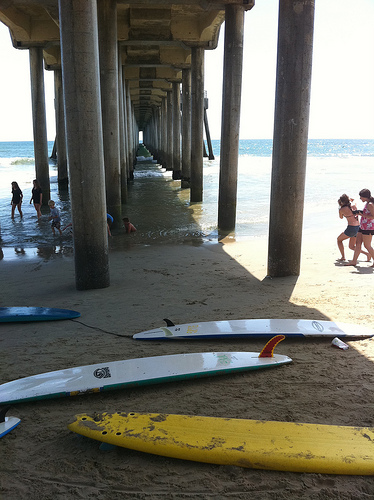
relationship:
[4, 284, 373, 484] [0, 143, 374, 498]
surfboards on beach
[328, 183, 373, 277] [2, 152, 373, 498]
girls walking on beach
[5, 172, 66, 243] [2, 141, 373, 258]
people in water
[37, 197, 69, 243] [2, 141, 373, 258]
child in water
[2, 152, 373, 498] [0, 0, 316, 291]
beach under dock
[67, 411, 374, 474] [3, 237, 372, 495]
surfboard on sand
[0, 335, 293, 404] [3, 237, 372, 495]
surfboard on sand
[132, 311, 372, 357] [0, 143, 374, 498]
surfboard on beach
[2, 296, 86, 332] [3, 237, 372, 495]
surfboard on sand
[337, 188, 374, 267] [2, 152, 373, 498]
girls on beach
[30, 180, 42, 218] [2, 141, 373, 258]
person on water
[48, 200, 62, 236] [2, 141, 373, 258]
child in water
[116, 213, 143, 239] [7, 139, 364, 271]
boy in water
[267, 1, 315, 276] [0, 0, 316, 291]
pillar for dock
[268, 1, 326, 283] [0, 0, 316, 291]
pillar for dock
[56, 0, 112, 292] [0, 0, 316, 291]
pillar for dock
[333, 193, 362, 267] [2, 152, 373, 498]
child on beach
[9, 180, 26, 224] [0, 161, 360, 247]
person wading in water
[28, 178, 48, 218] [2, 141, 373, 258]
person wading in water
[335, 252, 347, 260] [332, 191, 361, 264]
foot of child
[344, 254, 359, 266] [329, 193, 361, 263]
foot of child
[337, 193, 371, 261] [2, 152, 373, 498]
child on beach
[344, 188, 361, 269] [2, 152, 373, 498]
person on beach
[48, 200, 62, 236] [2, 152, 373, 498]
child on beach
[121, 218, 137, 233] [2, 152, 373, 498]
boy on beach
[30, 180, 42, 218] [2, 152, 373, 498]
person on beach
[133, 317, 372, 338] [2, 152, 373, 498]
surfboard on beach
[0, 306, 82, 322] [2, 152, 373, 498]
surfboard on beach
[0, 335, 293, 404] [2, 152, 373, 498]
surfboard on beach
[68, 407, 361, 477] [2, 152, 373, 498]
surfboard on beach